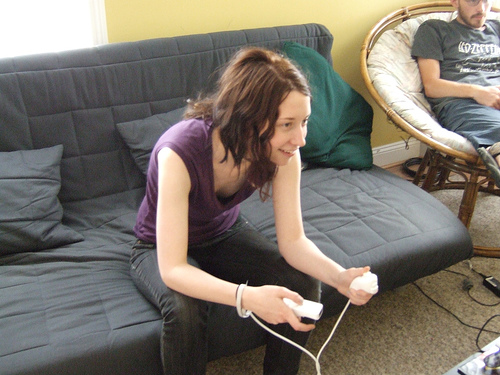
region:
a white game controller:
[285, 293, 330, 322]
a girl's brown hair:
[172, 46, 314, 207]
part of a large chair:
[357, 0, 497, 263]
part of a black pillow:
[0, 144, 89, 256]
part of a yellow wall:
[106, 2, 418, 143]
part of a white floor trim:
[368, 133, 423, 170]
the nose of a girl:
[287, 118, 307, 150]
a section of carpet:
[200, 157, 498, 373]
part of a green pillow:
[286, 50, 376, 169]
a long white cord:
[251, 314, 318, 369]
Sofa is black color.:
[50, 73, 340, 295]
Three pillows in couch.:
[5, 87, 372, 245]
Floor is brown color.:
[373, 315, 459, 365]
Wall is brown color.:
[111, 9, 207, 37]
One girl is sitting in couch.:
[128, 90, 378, 357]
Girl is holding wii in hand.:
[156, 223, 390, 370]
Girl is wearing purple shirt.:
[104, 110, 284, 264]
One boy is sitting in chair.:
[391, 10, 493, 140]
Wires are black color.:
[406, 250, 489, 347]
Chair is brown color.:
[354, 15, 486, 203]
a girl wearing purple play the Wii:
[129, 43, 386, 372]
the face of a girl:
[279, 92, 309, 169]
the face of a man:
[460, 0, 493, 32]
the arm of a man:
[416, 50, 498, 106]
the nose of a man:
[474, 2, 489, 15]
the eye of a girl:
[278, 118, 296, 131]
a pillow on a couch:
[1, 147, 80, 263]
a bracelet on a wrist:
[231, 280, 252, 322]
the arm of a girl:
[271, 179, 344, 278]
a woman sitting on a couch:
[132, 45, 377, 370]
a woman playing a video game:
[129, 52, 379, 374]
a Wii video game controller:
[247, 270, 379, 372]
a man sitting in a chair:
[361, 0, 499, 262]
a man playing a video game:
[414, 0, 499, 180]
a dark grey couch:
[0, 23, 474, 373]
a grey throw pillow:
[0, 144, 83, 259]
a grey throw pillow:
[117, 111, 209, 179]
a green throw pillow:
[279, 39, 376, 175]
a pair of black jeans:
[129, 210, 324, 373]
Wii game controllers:
[245, 271, 379, 373]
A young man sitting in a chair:
[413, 2, 498, 175]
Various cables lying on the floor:
[409, 251, 498, 351]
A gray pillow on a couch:
[0, 142, 81, 256]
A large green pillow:
[280, 39, 375, 171]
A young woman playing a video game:
[125, 46, 380, 373]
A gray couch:
[0, 22, 480, 373]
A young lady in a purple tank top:
[130, 51, 380, 373]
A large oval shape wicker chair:
[356, 0, 498, 255]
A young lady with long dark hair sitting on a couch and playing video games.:
[129, 47, 379, 373]